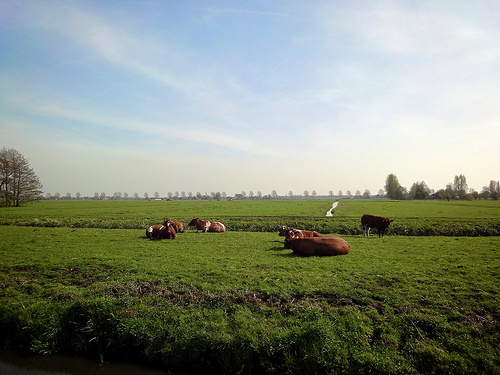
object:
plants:
[0, 147, 499, 372]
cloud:
[0, 0, 499, 195]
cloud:
[326, 1, 497, 88]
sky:
[0, 0, 499, 197]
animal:
[284, 236, 351, 256]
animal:
[360, 213, 391, 236]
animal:
[279, 226, 316, 234]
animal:
[187, 218, 227, 232]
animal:
[146, 223, 175, 239]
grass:
[0, 199, 498, 374]